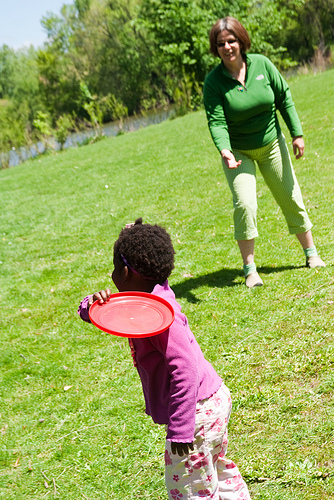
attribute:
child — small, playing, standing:
[83, 217, 245, 500]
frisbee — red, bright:
[85, 286, 175, 346]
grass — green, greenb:
[9, 68, 333, 491]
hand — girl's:
[90, 284, 114, 309]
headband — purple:
[109, 238, 167, 286]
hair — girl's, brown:
[111, 217, 177, 283]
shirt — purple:
[73, 286, 227, 439]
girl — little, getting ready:
[78, 217, 249, 498]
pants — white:
[158, 392, 253, 497]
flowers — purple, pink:
[171, 395, 242, 500]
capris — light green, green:
[228, 133, 312, 244]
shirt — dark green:
[201, 53, 302, 158]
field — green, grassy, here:
[8, 68, 333, 494]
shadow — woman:
[167, 262, 307, 304]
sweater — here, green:
[202, 55, 296, 168]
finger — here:
[225, 151, 233, 163]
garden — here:
[9, 0, 330, 486]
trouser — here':
[226, 138, 312, 243]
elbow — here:
[209, 115, 223, 129]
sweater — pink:
[80, 287, 226, 445]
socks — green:
[241, 248, 323, 286]